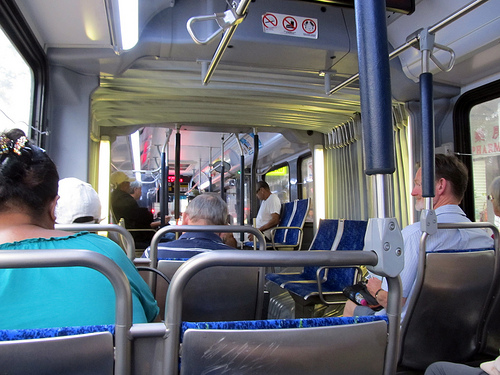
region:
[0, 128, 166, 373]
A woman in an aqua shirt sitting on a train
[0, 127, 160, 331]
A woman with her hair pulled up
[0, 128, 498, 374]
People sitting on a train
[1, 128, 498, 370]
Commuters riding in a train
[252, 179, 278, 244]
A man in a white shirt standing on a train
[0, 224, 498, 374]
Metal seats on a train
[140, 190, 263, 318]
A man in a blue and white striped shirt sitting on a train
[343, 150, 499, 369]
A man on a train looking to his left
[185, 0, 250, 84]
The handrail of a train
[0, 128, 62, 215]
Brown hair on a woman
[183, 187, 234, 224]
Gray hair on a man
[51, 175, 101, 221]
White hat on a person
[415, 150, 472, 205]
Brown hair on a man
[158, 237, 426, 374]
Seat on a bus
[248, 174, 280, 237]
Man sitting on a bus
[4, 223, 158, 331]
Teal shirt on a woman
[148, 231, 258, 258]
Blue shirt on a man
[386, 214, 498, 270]
Light colored shirt on a man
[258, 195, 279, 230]
White shirt on a man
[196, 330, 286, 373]
scuffed up area on a bus seat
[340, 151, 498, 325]
older man with black hair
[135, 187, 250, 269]
old man with light gray hair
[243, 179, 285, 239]
person wearing a white shirt and glasses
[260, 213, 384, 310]
blue and grey bench style seating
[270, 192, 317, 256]
blue and grey bench style seating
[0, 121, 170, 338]
lady with brown hair and blue shirt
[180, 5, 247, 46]
white safety handle for a bus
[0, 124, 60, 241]
Woman with brown hair tied with butterfly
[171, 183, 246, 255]
Man with grey hair sitting on bus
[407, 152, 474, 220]
Man with brown hair sitting on bus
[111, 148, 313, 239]
Group of people using the mass transit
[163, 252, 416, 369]
An empty seat on the bus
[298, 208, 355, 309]
Two empty blue seats on the bus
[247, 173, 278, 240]
Man with a hat standing on the bus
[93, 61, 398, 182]
Drapes dividing an area on the mass transit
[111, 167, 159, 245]
Two people sitting together on the mass transit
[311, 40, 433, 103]
Hand rail on the mass transit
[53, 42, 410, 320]
this is a train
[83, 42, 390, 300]
this is public transit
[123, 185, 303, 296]
the man is balding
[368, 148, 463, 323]
A person is sitting down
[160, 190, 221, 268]
A person is sitting down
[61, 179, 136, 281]
A person is sitting down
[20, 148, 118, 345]
A person is sitting down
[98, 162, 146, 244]
A person is sitting down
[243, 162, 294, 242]
A person is sitting down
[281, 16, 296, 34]
A sign on the wall.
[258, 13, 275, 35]
A sign on the wall.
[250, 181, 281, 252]
man sitting on the bus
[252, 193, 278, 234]
white tee shirt man is wearing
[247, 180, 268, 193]
black cap man is wearing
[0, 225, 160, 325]
turquoise colored top woman is wearing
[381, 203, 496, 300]
man wearing a light blue shirt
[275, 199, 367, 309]
empty blue seats on the bus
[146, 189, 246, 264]
man wearing a dark blue shirt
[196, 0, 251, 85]
passenger handlebar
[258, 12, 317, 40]
red, white and black hazardous sign above the passengers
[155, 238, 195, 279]
a view of iron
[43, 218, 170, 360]
a view of dress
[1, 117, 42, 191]
a view of hairs